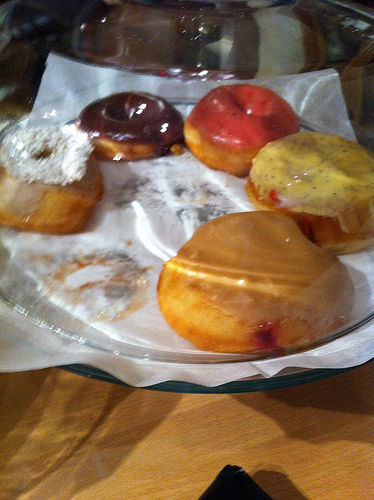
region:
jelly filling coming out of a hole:
[252, 323, 281, 349]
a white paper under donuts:
[0, 51, 371, 385]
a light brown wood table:
[1, 359, 373, 497]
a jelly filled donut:
[159, 208, 354, 348]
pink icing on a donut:
[191, 80, 302, 149]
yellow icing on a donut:
[248, 131, 373, 226]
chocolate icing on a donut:
[80, 88, 186, 159]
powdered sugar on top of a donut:
[3, 122, 90, 181]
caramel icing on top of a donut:
[183, 209, 359, 334]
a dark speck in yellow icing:
[310, 184, 320, 192]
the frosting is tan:
[232, 247, 266, 281]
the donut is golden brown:
[188, 307, 206, 327]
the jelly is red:
[254, 328, 273, 342]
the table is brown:
[287, 446, 330, 473]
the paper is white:
[192, 366, 216, 383]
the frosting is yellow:
[289, 155, 309, 168]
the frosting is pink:
[220, 112, 233, 133]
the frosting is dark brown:
[134, 118, 150, 131]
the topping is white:
[62, 139, 79, 163]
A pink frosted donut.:
[184, 84, 296, 175]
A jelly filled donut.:
[157, 211, 354, 354]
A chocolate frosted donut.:
[77, 88, 184, 157]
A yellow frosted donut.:
[246, 128, 373, 254]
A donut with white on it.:
[0, 123, 105, 230]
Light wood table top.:
[1, 362, 372, 497]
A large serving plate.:
[50, 365, 358, 391]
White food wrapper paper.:
[0, 51, 373, 389]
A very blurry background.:
[0, 0, 373, 144]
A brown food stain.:
[25, 238, 153, 328]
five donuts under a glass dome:
[2, 79, 373, 353]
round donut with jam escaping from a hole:
[152, 205, 357, 359]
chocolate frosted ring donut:
[75, 86, 186, 165]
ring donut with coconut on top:
[0, 120, 103, 235]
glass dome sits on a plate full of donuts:
[1, 0, 372, 393]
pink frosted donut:
[181, 79, 301, 181]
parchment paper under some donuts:
[4, 44, 372, 390]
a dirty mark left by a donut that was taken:
[20, 234, 156, 334]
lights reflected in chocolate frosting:
[126, 93, 182, 147]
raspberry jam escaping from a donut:
[244, 319, 285, 355]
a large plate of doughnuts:
[20, 67, 329, 374]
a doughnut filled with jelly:
[175, 219, 336, 344]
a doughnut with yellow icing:
[242, 137, 361, 226]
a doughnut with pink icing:
[195, 79, 275, 169]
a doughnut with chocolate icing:
[89, 75, 170, 157]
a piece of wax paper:
[16, 318, 90, 391]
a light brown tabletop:
[119, 418, 192, 487]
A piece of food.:
[160, 201, 352, 346]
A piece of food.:
[257, 128, 365, 238]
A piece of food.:
[194, 78, 297, 166]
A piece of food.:
[67, 72, 174, 151]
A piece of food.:
[10, 112, 111, 233]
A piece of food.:
[64, 149, 75, 160]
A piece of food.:
[59, 134, 68, 141]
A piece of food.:
[9, 144, 12, 150]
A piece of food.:
[33, 166, 40, 172]